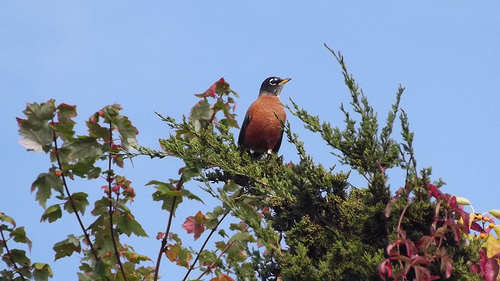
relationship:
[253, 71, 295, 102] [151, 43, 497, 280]
bird in trees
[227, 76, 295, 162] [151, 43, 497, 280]
bird in trees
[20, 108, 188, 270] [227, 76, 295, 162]
tree behind bird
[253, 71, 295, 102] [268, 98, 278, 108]
bird has breast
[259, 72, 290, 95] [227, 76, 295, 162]
head of bird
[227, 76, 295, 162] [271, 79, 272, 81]
bird has markings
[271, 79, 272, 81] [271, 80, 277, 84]
markings around eye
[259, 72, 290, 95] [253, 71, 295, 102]
head of bird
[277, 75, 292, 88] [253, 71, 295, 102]
beak of bird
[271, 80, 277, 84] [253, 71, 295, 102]
eye of bird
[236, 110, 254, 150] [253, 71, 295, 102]
wings of bird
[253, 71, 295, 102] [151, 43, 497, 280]
bird on trees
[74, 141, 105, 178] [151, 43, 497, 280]
leaf on trees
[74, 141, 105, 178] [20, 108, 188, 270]
leaf on tree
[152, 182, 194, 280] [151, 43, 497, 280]
branch of trees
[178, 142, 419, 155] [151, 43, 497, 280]
top of trees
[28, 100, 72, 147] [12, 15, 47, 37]
leaves against sky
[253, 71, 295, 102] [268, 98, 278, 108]
bird with breast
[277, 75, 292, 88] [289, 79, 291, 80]
beak has tip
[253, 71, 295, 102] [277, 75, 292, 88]
bird with beak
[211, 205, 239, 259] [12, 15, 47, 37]
branches against sky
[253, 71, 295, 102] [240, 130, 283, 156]
bird with wings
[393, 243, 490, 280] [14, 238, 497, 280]
foliage from trees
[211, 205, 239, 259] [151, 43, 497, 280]
branches from trees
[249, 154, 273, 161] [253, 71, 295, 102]
feet of bird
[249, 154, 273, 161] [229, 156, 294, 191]
feet grasping branch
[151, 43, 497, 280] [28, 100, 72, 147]
trees with leaves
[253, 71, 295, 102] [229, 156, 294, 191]
bird on branch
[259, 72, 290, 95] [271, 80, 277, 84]
head with eye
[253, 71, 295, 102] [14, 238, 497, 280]
bird above trees